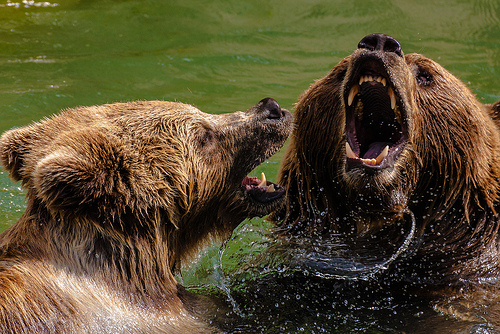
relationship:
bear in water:
[28, 88, 300, 328] [32, 10, 366, 160]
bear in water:
[210, 30, 493, 334] [32, 10, 366, 160]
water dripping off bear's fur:
[205, 250, 310, 330] [174, 210, 248, 268]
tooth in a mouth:
[338, 86, 365, 120] [314, 17, 441, 231]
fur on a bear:
[121, 128, 199, 226] [19, 80, 331, 303]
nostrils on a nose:
[374, 28, 401, 58] [350, 22, 404, 63]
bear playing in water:
[270, 30, 493, 226] [65, 4, 395, 149]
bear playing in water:
[0, 97, 300, 332] [65, 4, 395, 149]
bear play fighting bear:
[0, 97, 300, 332] [210, 30, 493, 334]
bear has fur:
[0, 97, 300, 332] [58, 176, 158, 326]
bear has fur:
[282, 36, 498, 305] [429, 137, 484, 222]